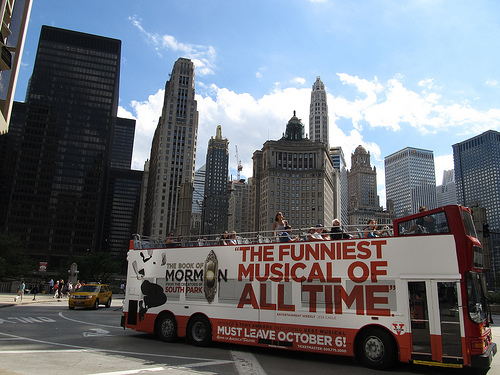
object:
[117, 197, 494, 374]
bus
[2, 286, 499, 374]
road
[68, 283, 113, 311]
cab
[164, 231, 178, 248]
passenger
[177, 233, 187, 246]
passenger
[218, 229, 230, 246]
passenger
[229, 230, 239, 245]
passenger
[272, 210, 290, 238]
passenger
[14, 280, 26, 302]
people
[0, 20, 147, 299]
building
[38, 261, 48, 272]
advertisement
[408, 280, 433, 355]
door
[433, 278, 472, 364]
door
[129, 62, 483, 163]
clouds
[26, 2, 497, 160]
sky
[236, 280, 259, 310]
words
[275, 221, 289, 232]
shirt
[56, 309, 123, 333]
lines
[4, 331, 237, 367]
lines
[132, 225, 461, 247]
floor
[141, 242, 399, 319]
advertisement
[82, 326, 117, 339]
arrow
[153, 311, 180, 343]
wheel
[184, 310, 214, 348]
wheel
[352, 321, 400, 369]
wheel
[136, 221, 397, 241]
railing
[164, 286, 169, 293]
words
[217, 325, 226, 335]
words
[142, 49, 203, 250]
building